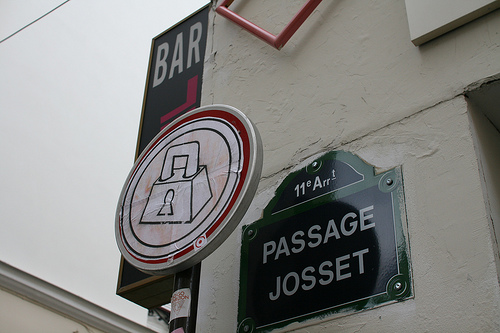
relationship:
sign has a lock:
[114, 104, 264, 276] [138, 142, 215, 225]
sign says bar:
[138, 0, 216, 160] [150, 22, 204, 89]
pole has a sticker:
[170, 262, 202, 332] [165, 287, 193, 322]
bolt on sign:
[394, 281, 404, 291] [239, 150, 427, 331]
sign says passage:
[239, 150, 427, 331] [264, 204, 386, 268]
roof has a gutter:
[0, 251, 182, 332] [4, 264, 158, 332]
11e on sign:
[291, 176, 312, 198] [239, 150, 427, 331]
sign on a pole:
[114, 104, 264, 276] [170, 262, 202, 332]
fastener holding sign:
[385, 176, 395, 186] [239, 150, 427, 331]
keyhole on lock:
[157, 188, 174, 217] [138, 142, 215, 225]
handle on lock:
[157, 140, 201, 178] [138, 142, 215, 225]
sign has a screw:
[239, 150, 427, 331] [385, 176, 395, 186]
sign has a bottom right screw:
[239, 150, 427, 331] [394, 281, 404, 291]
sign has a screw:
[239, 150, 427, 331] [242, 324, 249, 332]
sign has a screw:
[239, 150, 427, 331] [246, 228, 256, 237]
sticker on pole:
[165, 287, 193, 322] [170, 262, 202, 332]